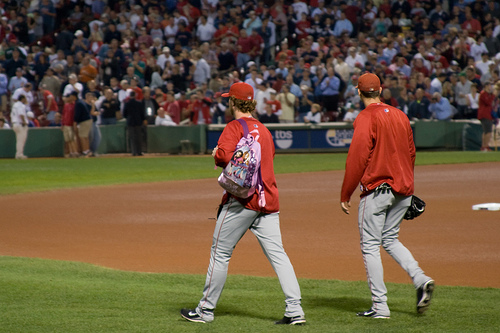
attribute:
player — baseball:
[339, 68, 442, 324]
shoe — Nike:
[355, 305, 391, 322]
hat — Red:
[351, 70, 382, 93]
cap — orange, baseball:
[219, 76, 255, 102]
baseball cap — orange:
[343, 64, 404, 116]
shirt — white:
[303, 110, 321, 122]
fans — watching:
[126, 31, 473, 112]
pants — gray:
[207, 217, 296, 314]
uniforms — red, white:
[174, 67, 436, 327]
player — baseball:
[182, 84, 304, 330]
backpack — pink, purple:
[218, 119, 262, 196]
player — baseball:
[334, 72, 434, 322]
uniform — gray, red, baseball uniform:
[337, 100, 430, 308]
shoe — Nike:
[349, 304, 395, 321]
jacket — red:
[339, 101, 419, 201]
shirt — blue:
[317, 74, 341, 94]